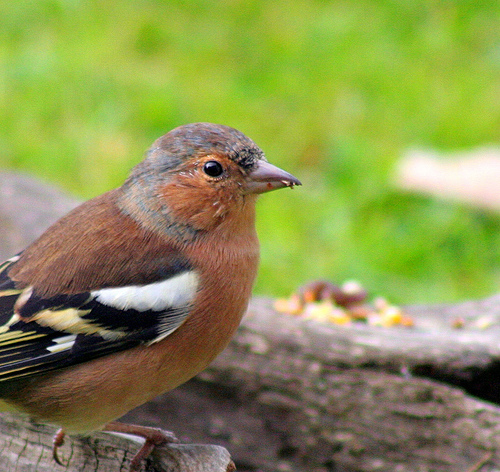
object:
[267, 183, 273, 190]
blood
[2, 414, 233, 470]
rock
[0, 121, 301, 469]
bird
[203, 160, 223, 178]
eye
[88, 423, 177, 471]
feet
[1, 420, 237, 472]
bench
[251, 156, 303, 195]
beak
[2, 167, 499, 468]
tree log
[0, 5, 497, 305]
grass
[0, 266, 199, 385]
feathers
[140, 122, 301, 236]
head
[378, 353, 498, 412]
hole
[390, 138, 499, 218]
foot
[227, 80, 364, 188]
leaves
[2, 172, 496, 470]
log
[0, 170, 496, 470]
ledge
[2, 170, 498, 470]
tree branch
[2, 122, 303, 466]
animal